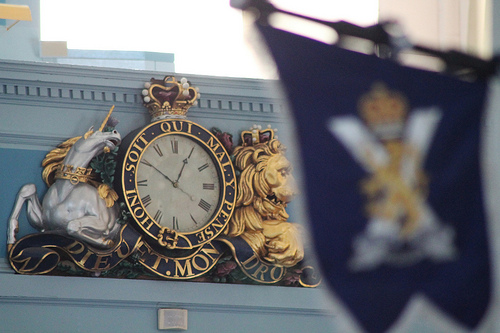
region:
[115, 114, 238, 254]
the frame of a clock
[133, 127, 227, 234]
the face of a clock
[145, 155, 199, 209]
the hands of a clock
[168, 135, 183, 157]
a number on the clock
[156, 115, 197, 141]
writing on the clock frame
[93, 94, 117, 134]
the horn of a unicorn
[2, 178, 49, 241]
the leg of a unicorn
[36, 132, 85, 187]
the mane of a unicorn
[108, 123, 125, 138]
the nose of a unicorn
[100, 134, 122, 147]
the mouth of a unicorn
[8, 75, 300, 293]
roman numeral clock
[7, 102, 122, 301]
white unicorn with gold horn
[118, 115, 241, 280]
gold and black clock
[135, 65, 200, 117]
two crowns at top of clock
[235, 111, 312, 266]
crown on top of lion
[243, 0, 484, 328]
heritage flag black with a white x and fuzzy picture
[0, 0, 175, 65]
group of buildings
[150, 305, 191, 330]
square below clock building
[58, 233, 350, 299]
in French God and my Right in gold lettering on clock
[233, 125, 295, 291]
gold lion wearing a crown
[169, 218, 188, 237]
roman numeral on clock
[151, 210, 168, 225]
roman numeral on clock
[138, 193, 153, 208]
roman numeral on clock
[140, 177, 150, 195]
roman numeral on clock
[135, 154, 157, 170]
roman numeral on clock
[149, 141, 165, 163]
roman numeral on clock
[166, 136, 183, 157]
roman numeral on clock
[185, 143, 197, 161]
roman numeral on clock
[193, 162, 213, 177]
roman numeral on clock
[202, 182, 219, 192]
roman numeral on clock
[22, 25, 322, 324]
a clock that is outside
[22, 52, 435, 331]
a clock with a silver horse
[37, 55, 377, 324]
a clock with silver horse with gold hiar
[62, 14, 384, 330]
a clock with a lion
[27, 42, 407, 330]
a clock with a gold lion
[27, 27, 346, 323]
a clock on a building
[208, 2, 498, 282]
a flag hanging on pole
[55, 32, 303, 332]
a clock with gold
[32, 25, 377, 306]
an outside clock on building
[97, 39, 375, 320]
a clock on top of building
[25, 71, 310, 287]
gold clock on wall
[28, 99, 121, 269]
silver unicorn on gold clock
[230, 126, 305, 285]
gold lion on gold clock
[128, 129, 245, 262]
face of gold clock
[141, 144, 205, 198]
hands of clock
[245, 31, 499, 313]
blue flag in front of clock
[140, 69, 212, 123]
crown on top of clock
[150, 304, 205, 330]
motion sensor on wall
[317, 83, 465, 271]
image on flag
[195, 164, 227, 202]
roman numerals on clock